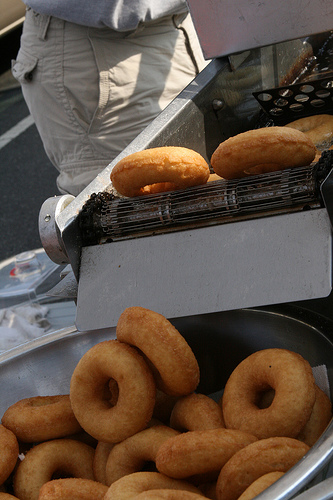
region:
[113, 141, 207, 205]
a golden donut exits the fryer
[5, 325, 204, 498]
yummy looking donuts in a bowl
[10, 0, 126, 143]
a person's right hip pocket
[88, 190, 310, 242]
a chain driven conveyor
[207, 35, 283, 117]
a reflection of a donut frying in oil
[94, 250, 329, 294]
stainless steel direction chute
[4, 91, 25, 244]
asphalt with white painted line in background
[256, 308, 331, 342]
rim of a stainless steel bowl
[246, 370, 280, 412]
a regular hole in a donut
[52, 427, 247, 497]
donuts without any frosting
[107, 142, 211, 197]
a unglazed donut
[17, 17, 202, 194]
brown cargo shorts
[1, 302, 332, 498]
a bowl full of donuts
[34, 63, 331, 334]
a silver frying machine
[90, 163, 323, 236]
a rolling track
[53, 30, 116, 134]
a side pocket in the shorts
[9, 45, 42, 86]
a back pocket in the shorts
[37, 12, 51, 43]
a belt loop of the shorts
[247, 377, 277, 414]
a hole in the donut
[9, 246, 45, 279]
a knob on the frying machine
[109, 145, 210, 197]
a golden brown donut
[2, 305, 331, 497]
donuts in a metal bowl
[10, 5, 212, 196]
white shorts with pockets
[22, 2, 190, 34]
part of a gray t-shirt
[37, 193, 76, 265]
a gray metal knob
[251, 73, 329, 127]
a metal thing with holes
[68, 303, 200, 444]
two golden brown donuts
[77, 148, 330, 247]
a roller with a chain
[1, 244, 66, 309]
a metal container with a lid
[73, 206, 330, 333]
a silver metal plate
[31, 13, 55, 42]
belt loop on tan pants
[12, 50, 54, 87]
back pocket on tan pants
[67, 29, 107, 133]
side pocket on tan pants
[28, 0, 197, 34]
portion of blue shirt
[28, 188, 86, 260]
large silver knob on fryer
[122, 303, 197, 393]
fried donut in bowl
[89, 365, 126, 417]
round donut hole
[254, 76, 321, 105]
slats on silver fryer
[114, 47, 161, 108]
deep creases on man's tan pants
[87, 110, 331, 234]
doughnuts are falling from a conveyer belt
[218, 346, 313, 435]
the doughnuts are circular in shape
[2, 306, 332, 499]
doughnuts are sitting in a large metal container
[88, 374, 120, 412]
the doughnuts have circular holes in the center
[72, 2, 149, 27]
person wearing a grey shirt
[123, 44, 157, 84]
person wearing tan clothing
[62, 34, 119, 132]
pocket on an article of clothing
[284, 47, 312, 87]
brown buildup inside a large machine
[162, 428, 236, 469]
the doughnuts are unglazed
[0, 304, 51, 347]
a rag sits near the doughnuts